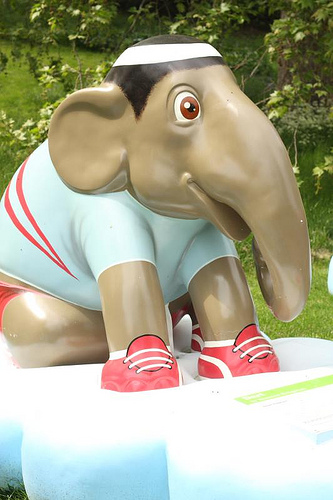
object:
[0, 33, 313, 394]
statue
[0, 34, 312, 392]
elephant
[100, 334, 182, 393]
shoes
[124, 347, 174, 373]
shoelaces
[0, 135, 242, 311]
shirt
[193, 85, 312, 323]
trunk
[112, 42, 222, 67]
headband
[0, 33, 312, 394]
grass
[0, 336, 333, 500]
platform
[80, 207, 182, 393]
leg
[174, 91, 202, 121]
eye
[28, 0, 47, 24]
leaves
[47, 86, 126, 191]
ear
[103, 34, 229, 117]
hair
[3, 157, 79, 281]
red stripe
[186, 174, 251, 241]
mouth